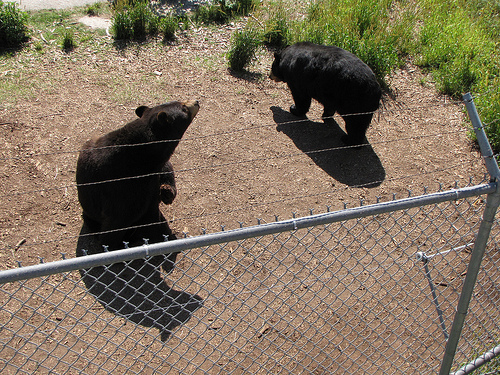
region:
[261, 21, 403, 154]
the black bear in the forest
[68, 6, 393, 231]
two black bares beside the fencing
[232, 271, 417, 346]
the mesh used as fencing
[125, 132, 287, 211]
the wired fencing used for protection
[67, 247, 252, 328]
the shadow of the bear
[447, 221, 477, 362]
the rods used for support of the fencing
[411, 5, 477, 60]
the green grass in the fields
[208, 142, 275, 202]
the brown colored soil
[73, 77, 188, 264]
a black colored bear sitting on one leg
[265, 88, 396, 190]
the shadow of the bear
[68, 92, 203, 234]
Brown bear scratching himself.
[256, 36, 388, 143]
Brown bear walking away.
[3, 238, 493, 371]
Metal chain link fencing.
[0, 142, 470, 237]
Barbed wire on top of fencing.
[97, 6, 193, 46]
Green tuffs of grass.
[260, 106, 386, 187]
Bear's shadow on the ground.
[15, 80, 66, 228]
Dry and dusty dirt.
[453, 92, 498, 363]
Aluminum supporting post.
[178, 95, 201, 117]
Snout of a bear.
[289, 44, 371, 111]
Thick black bear fur.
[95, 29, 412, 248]
two large bears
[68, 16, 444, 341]
bears behind chain link fence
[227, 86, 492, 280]
chain link fence and barbed wire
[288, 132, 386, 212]
shadow on ground made by bear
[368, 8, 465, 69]
bright green shrubbery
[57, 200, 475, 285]
silver bar of chain link fence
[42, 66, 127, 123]
ground covered with twigs and dirt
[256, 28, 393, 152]
black bear looking at ground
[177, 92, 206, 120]
light brown and black nose of bear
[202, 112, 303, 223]
three strings of barbed wire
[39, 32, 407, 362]
Two bears in fenced in area.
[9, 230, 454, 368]
A chain link fence.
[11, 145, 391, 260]
Barbed wire across top of fence.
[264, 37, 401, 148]
A black bear on the right.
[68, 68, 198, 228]
A black bear on the left.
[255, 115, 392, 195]
Shadow of bear on the right.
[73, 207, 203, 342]
Shadow of bear on left.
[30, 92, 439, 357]
An area of dirt with no grass.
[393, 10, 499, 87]
Green grass on the side.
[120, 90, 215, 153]
Head of the bear on the left.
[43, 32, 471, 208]
two bears in the picture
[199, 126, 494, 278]
a fence with barbed wire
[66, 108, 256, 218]
the bear is brown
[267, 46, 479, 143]
the bear is black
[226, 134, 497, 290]
brown dirt on ground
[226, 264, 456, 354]
linked fence to protect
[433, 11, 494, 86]
the grass is tall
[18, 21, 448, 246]
besides bears there are no other animals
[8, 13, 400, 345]
there are no people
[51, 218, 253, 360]
the bear's shadow is present